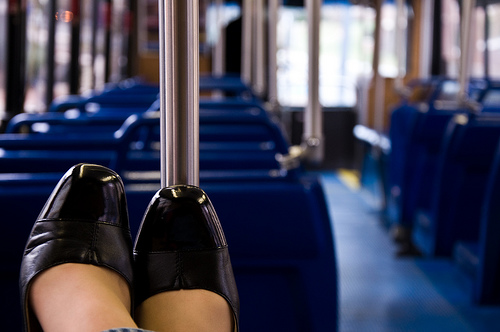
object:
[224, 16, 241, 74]
person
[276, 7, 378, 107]
window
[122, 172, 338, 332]
blue seats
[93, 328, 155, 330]
jeans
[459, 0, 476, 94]
pole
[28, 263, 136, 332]
feet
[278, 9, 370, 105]
lights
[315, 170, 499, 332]
walkway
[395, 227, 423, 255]
legs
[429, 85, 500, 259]
seat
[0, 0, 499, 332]
bus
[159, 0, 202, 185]
pole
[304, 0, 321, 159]
pole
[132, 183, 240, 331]
shoe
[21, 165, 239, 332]
woman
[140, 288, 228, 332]
foot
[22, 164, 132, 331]
black pumps